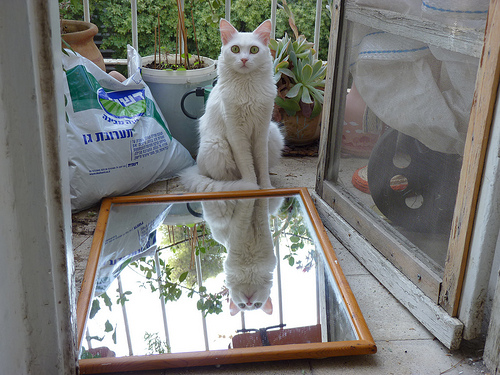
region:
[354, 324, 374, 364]
edge of a mirror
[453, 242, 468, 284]
part of a door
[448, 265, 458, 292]
edge of a door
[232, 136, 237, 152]
leg of a cat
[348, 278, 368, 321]
part of a frame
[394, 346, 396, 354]
part of the floor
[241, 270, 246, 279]
part of a reflection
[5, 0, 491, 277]
a white cat in front a door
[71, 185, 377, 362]
reflection of a cat on a mirror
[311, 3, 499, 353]
an old door of wood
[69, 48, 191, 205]
a white bag is full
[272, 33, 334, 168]
pot with plant behind the car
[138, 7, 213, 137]
plants on a white pail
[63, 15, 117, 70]
an empty pot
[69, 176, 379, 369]
frame of window is brown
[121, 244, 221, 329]
branches reflected on mirror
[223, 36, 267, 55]
eyes of cat are round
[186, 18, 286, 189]
a fluffy white cat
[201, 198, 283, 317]
the reflection of a fluffy white cat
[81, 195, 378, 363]
a brown framed mirror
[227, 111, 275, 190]
a pair of cat legs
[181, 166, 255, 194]
a white fluffy cat tail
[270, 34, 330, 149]
a potted plant in a pot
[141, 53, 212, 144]
a white bucket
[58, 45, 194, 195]
a white bag of potting soil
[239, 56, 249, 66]
a cat's pink nose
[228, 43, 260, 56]
a pair of green eyes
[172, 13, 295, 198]
Cat is sitting down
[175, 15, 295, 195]
White cat is sitting down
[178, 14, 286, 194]
Cat is in front of mirror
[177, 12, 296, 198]
White cat in front of mirror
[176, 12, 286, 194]
Cat sitting down in front of mirror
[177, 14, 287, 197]
White cat sitting down in front of mirror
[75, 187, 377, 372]
Mirror is on the floor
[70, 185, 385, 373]
Mirror is on the ground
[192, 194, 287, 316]
Reflection of cat in the mirror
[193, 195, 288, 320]
Reflection of white cat in the mirror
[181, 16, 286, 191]
a fuzzy white cat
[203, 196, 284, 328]
cats reflection in a mirror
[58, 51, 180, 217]
a bag of potting soil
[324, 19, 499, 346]
a opened door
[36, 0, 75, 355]
a wooden door facing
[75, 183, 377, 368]
a wooden frame around mirror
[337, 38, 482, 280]
a screen in panel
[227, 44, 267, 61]
a white cats eyes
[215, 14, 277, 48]
a white cats ears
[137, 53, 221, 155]
a white bucket